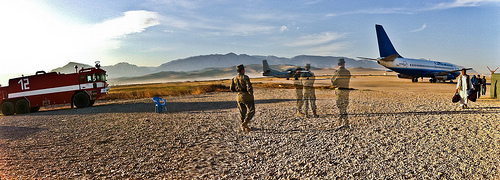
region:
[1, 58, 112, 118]
red vehicle with number 12 on it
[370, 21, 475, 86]
light colored jet plane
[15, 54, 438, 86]
mountain range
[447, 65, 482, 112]
man in white carrying bags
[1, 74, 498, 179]
a dry flat plains area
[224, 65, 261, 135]
a man in a jumpsuit standing with 1 leg bent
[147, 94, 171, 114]
a light blue chair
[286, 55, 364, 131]
3 men in jumpsuits that look translucent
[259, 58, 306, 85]
a plane that looks see-through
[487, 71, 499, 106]
an item covered in green cloth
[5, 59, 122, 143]
Red and white truck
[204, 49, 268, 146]
Military man walking in the dirt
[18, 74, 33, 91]
White number 12 on red truck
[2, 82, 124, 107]
White stripe on red truck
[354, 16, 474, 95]
Blue and white airplane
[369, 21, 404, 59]
Large blue wing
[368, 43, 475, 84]
White body of airplane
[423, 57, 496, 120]
Group of people walking to the airplane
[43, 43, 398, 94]
Mountains in the distance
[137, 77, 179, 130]
Small blue plastic chair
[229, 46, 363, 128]
military men at a landing strip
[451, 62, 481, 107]
a man carrying black suitcases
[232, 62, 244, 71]
a hat on a head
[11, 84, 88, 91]
a white stripe on a fire truck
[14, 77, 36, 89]
a white number on a fire truck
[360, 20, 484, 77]
a large blue and silver jet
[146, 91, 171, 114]
a blue plastic chair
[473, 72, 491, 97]
people following a man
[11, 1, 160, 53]
white cloud in the sky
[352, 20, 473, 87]
Airplane on the ground.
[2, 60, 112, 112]
Firetruck on the gravel.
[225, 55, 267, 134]
Man standing on the ground.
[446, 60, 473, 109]
Person carrying a black bag.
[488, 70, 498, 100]
Green tent in the background.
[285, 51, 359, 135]
Reflection of men in the background.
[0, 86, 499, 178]
Gravel on the ground.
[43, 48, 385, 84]
Mountains in the background.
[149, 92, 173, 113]
Blue chair on the ground.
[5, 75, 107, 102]
White stripe on the firetruck.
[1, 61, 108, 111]
Firetruck parked to the side of the airstrip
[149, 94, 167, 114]
Blue plastic chair sitting there for no apparent reason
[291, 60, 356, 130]
Three ghost like soldiers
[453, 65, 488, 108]
People on the right who appear to be disembarking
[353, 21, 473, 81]
An airplane that seems to be parked to the right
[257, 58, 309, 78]
A distant airplane that appears to be taking off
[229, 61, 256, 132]
The solider in the middle who is not semi-transparent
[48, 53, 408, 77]
Distant mountain range in the background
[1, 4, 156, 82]
Bank of clouds on the far left of the photo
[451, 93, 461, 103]
Black suit case being carried in a man's right hand